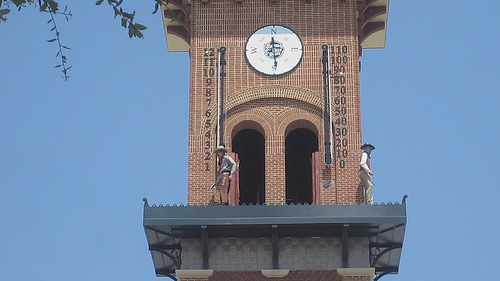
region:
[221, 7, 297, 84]
white clock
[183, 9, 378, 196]
brwon clock tower with white clock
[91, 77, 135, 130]
white clouds in blue sky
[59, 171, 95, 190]
white clouds in blue sky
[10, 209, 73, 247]
white clouds in blue sky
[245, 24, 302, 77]
A clock that looks like a compass.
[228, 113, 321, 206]
Two dark archways under a compass clock.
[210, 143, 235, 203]
A cowboy with a hat on in front of an arched way.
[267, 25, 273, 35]
A large N on a clock top.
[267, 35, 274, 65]
A long black hand of a compass.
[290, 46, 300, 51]
A large E on a compass.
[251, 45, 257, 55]
Large black W on a compass.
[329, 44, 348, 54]
A black 110 on a brick wall.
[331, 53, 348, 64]
A black 100 on a brick wall.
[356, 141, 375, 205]
A cowboy over by the number 0.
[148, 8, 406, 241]
light brown clock tower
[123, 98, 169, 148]
white clouds in blue sky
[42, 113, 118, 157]
white clouds in blue sky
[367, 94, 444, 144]
white clouds in blue sky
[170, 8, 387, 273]
brown clock tower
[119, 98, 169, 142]
white clouds in blue sky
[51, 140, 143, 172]
white clouds in blue sky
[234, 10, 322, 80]
clock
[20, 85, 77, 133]
white clouds in blue sky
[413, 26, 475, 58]
white clouds in blue sky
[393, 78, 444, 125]
white clouds in blue sky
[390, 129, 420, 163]
white clouds in blue sky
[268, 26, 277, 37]
Black N on a clock top.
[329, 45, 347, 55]
Black number 110 next to a compass.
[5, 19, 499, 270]
The clear blue sky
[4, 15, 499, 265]
A clear blue sky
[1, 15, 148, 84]
The piece of tree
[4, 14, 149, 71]
A piece of tree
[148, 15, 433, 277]
The red brick building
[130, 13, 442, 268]
A red brick building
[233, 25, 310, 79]
A clock on the building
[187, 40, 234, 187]
The numbers to the left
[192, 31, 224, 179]
A set of numbers to the left